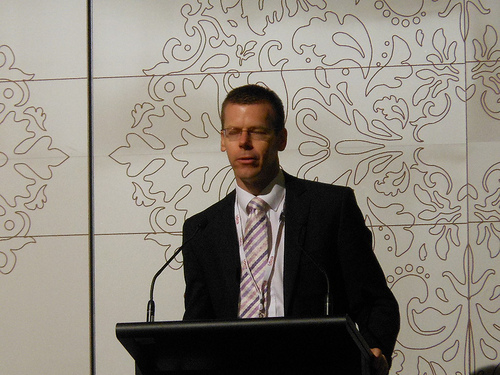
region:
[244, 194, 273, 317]
a striped tie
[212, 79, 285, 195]
a man wearing glasses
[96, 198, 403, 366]
a podium with a microphone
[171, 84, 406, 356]
a man speaking to a group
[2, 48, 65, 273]
detailed artwork on the wall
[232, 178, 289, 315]
mens white dress shirt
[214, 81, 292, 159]
shorts mens hair cut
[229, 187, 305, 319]
ID neck lanyard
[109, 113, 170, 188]
brown artsy outline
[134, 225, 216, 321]
microphone that man is speaking into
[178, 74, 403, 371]
man at a podium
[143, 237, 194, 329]
small microphone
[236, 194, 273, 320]
light colored striped tie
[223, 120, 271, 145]
man's pair of eyeglasses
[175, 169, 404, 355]
dark colored suit jacket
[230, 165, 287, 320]
white buttoned down shirt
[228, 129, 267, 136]
man's closed eyelids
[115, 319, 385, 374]
black podium stand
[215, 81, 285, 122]
short medium brown hair on man's head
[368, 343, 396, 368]
hand holding on to podium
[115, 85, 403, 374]
A man with his eyes closed.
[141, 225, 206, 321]
A microphone for speakers.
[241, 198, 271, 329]
The Colorful striped tie.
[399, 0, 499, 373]
A grey artistically designed wall.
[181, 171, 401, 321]
A black suit jacket.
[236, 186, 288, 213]
The white collar of his shirt.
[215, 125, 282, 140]
The man wearing clear glasses.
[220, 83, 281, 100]
The man's short brown hair.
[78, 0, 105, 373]
The black separation of wall.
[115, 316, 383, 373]
The speaker's black podium.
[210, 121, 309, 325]
man is wearing a lanyard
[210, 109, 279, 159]
man is wearing a eyeglass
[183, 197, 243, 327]
the coat is black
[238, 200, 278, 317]
the necktie is stripes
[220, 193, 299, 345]
the shirt is white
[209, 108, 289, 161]
man's eyes are closed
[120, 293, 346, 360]
the podium is black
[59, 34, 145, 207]
the wall is white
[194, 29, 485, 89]
the wall has prints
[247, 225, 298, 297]
the lanyard is white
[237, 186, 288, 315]
lanyard around mans neck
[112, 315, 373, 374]
podium in front of man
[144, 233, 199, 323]
black microphone on podium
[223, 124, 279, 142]
glasses on mans face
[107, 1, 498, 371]
wavy design on backboard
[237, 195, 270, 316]
striped tie around mans neck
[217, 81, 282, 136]
short dark hair on head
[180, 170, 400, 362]
smart black suit jacket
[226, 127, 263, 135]
eyes are closed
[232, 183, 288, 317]
smart white dress shirt